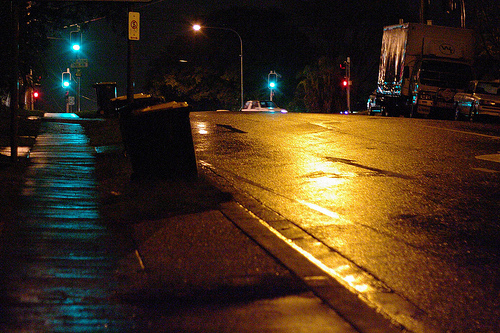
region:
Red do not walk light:
[341, 79, 348, 86]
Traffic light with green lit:
[268, 71, 278, 88]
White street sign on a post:
[124, 9, 140, 43]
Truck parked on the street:
[375, 22, 475, 117]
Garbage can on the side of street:
[91, 78, 118, 114]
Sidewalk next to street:
[23, 110, 122, 330]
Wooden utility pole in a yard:
[10, 0, 22, 162]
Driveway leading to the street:
[1, 141, 156, 154]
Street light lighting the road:
[189, 24, 204, 32]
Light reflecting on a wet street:
[196, 111, 498, 331]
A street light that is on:
[186, 16, 258, 111]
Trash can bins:
[112, 78, 203, 181]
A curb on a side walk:
[221, 182, 416, 327]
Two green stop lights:
[61, 31, 88, 106]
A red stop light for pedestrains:
[336, 52, 356, 112]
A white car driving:
[233, 89, 295, 120]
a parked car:
[446, 59, 499, 129]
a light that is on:
[189, 24, 210, 36]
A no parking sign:
[121, 2, 149, 49]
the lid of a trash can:
[90, 76, 121, 93]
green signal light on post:
[60, 75, 73, 90]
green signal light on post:
[70, 38, 88, 57]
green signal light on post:
[264, 78, 288, 93]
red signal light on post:
[333, 77, 352, 95]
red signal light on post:
[29, 89, 46, 108]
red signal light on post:
[187, 18, 202, 38]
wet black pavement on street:
[224, 136, 281, 179]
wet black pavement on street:
[285, 150, 350, 193]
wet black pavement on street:
[365, 171, 433, 236]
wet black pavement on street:
[308, 114, 404, 170]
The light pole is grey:
[333, 53, 368, 119]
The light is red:
[328, 54, 359, 100]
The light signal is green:
[261, 63, 293, 124]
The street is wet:
[193, 94, 460, 307]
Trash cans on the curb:
[98, 78, 214, 195]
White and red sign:
[121, 10, 151, 43]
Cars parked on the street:
[378, 17, 488, 119]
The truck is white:
[371, 22, 472, 122]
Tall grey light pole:
[185, 12, 256, 107]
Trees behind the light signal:
[188, 52, 360, 106]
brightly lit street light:
[191, 20, 251, 110]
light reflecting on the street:
[261, 117, 381, 303]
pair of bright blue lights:
[56, 28, 87, 95]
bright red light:
[341, 74, 350, 93]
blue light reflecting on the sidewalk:
[34, 114, 103, 330]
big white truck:
[377, 14, 481, 117]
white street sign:
[120, 8, 147, 92]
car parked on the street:
[454, 77, 498, 119]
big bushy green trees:
[148, 17, 358, 111]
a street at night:
[36, 10, 461, 320]